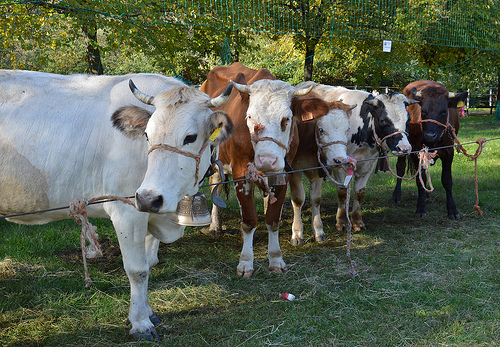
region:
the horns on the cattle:
[123, 68, 315, 110]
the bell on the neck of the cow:
[171, 193, 216, 228]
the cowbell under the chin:
[264, 166, 291, 194]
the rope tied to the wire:
[58, 188, 117, 293]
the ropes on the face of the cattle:
[378, 103, 490, 233]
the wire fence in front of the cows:
[378, 135, 498, 165]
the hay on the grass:
[303, 243, 455, 345]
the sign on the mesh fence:
[378, 31, 397, 58]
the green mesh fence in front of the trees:
[393, 0, 498, 47]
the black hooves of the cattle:
[136, 308, 158, 344]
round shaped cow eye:
[143, 131, 148, 141]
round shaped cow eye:
[183, 132, 199, 147]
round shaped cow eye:
[246, 111, 253, 121]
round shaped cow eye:
[285, 113, 292, 124]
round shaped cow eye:
[317, 125, 325, 136]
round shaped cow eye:
[378, 115, 384, 127]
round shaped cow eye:
[439, 106, 449, 115]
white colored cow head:
[104, 72, 235, 217]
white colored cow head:
[241, 78, 295, 175]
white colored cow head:
[314, 108, 354, 165]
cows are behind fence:
[70, 44, 472, 232]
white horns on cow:
[128, 58, 252, 190]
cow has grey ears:
[101, 100, 208, 135]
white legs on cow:
[101, 197, 169, 341]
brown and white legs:
[224, 170, 274, 264]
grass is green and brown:
[274, 263, 458, 338]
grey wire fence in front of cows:
[65, 154, 397, 262]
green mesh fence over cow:
[178, 0, 490, 77]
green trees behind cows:
[127, 10, 494, 101]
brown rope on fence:
[38, 198, 138, 258]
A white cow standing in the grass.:
[1, 67, 232, 337]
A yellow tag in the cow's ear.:
[206, 123, 221, 141]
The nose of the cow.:
[135, 190, 163, 213]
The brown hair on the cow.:
[210, 73, 230, 91]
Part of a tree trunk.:
[303, 37, 315, 82]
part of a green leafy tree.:
[151, 28, 188, 63]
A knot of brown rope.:
[69, 198, 102, 286]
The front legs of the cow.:
[103, 200, 159, 340]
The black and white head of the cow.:
[365, 90, 411, 153]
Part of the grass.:
[38, 300, 98, 336]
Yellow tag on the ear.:
[207, 117, 225, 143]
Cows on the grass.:
[2, 50, 479, 345]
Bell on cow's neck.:
[171, 188, 217, 228]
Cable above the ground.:
[0, 126, 492, 223]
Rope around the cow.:
[243, 135, 292, 159]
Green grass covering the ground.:
[6, 105, 495, 345]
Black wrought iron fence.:
[87, 0, 494, 57]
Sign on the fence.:
[379, 35, 393, 54]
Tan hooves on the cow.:
[230, 260, 290, 280]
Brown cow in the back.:
[396, 73, 465, 218]